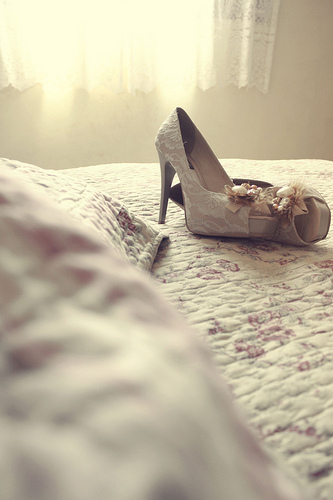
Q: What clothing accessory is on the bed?
A: Shoes.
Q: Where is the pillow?
A: On the bed.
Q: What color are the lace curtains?
A: White.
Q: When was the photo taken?
A: During daylight hours.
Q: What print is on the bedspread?
A: Floral print.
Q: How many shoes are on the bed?
A: Two.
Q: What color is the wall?
A: White.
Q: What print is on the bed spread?
A: Floral.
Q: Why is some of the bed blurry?
A: Out of focus.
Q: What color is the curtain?
A: White.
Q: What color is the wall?
A: White.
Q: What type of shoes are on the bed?
A: High heels.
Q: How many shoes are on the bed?
A: Two.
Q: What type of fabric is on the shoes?
A: Lace.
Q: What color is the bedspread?
A: White.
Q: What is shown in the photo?
A: An open toed shoe.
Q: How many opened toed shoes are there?
A: There are two open toed shoes.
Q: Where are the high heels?
A: The high heels are on the bed.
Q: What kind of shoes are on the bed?
A: There are wedding shoes on the bed.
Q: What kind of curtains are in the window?
A: There are lace curtains in the window.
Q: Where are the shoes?
A: They are on the bed.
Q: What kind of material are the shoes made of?
A: The shoes are made of lace.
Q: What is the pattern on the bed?
A: There is a floral pattern on the bed.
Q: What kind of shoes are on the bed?
A: There are high heeled shoes on bed.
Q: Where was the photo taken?
A: In a bedroom.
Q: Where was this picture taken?
A: On a bed.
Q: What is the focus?
A: Shoes.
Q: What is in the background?
A: Curtains.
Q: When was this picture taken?
A: Daytime.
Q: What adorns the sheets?
A: Flowers.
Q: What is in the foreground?
A: A pillow.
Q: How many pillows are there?
A: 2.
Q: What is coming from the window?
A: Sunlight.